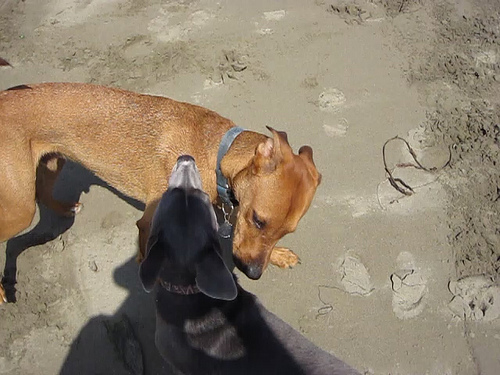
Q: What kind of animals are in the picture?
A: Dogs.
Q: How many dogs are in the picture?
A: Two.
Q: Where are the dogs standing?
A: The sand.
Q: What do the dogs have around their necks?
A: Collars.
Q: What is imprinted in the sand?
A: Footprints.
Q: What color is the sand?
A: Tan.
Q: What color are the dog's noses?
A: Black.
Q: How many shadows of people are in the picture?
A: One.